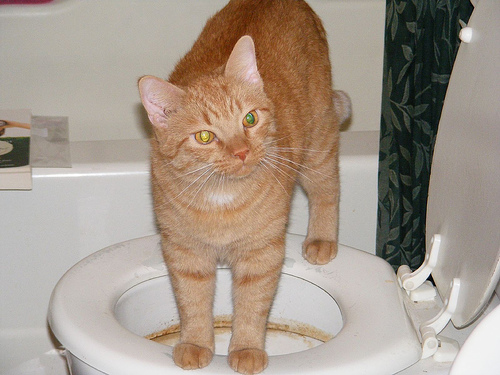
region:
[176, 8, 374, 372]
cat standing on toilet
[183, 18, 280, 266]
cat is a orange tabby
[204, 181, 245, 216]
white spot on the cat's chest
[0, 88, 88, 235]
book on the tub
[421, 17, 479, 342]
toilet seat is up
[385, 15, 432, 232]
shower curtain is green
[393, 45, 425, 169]
leaves on the design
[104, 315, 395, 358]
dirt ring in the toilet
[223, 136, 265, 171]
cat's nose is pink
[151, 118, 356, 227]
cat whiskers are white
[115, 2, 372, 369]
a brown cat over a toilet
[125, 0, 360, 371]
cat stand on a toilet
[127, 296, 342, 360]
the inside of a toilet is dirt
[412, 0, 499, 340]
lid of a toilet is up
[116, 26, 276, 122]
pointy ears of a cat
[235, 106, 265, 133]
a cat has a green eye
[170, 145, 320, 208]
whiskers of a cat is white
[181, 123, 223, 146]
eye of a cat is yellow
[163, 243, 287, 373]
front legs of a cat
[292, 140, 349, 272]
back leg of a cat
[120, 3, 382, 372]
the cat is orange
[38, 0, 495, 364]
the cat is standing on the toilet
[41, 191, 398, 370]
the toilet is dirty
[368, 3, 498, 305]
the shower curtain is green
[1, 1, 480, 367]
a bathtub beside the toilet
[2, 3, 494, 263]
the bathtub is white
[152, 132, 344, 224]
the whiskers are white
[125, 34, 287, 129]
the cat has ears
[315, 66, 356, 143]
the cat has a tail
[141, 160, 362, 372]
the cat has legs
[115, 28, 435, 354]
the cat is brown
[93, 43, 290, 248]
the cat is brown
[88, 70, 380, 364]
the cat is brown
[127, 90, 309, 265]
the cat is brown